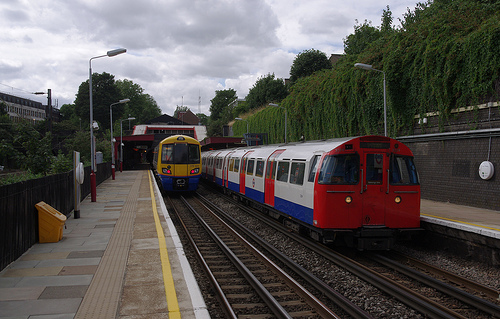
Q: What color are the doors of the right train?
A: Red.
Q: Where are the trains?
A: On the tracks.